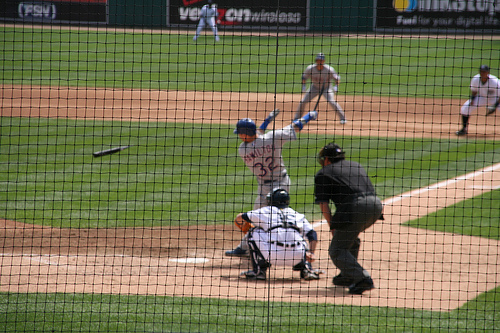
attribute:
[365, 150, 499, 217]
line — white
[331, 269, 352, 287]
shoe — black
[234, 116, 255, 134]
helmet — blue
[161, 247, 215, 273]
homeplate — white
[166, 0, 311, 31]
banner — sponser banner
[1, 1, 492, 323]
fence — black, metal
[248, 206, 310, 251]
shirt — white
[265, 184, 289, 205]
mask — black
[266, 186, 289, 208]
helmet — black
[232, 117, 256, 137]
hat — blue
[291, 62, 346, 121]
uniform — grey, blue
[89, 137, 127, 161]
bat — black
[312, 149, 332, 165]
mask — black